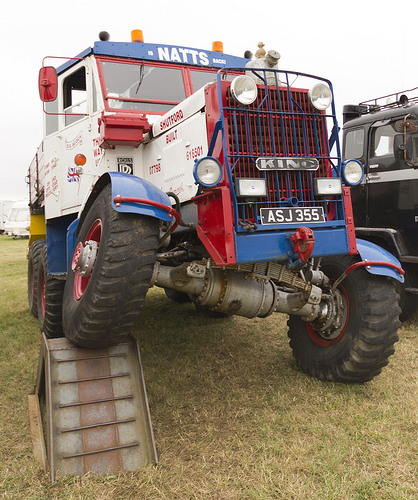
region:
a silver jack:
[38, 335, 159, 472]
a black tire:
[290, 246, 398, 379]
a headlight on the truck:
[195, 159, 220, 185]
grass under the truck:
[161, 382, 415, 496]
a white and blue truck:
[24, 35, 401, 377]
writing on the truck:
[155, 47, 216, 64]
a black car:
[345, 96, 416, 248]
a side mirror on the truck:
[39, 59, 88, 114]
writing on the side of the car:
[32, 120, 229, 203]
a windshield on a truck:
[101, 57, 186, 109]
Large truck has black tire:
[21, 27, 403, 382]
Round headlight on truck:
[229, 76, 258, 105]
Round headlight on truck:
[192, 157, 221, 186]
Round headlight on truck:
[342, 159, 363, 184]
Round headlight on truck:
[307, 82, 332, 113]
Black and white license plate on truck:
[260, 207, 326, 223]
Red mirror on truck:
[39, 66, 58, 99]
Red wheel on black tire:
[71, 218, 102, 301]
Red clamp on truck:
[292, 224, 315, 263]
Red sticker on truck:
[156, 107, 185, 130]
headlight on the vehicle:
[185, 151, 222, 186]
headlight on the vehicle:
[338, 159, 368, 190]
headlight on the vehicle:
[219, 77, 260, 103]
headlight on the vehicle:
[306, 90, 337, 115]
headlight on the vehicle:
[235, 180, 272, 192]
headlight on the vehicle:
[315, 178, 340, 198]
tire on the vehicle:
[57, 204, 169, 346]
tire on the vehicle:
[297, 273, 397, 403]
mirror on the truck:
[31, 62, 65, 107]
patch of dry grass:
[233, 454, 262, 482]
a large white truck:
[24, 30, 403, 385]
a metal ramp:
[24, 331, 157, 482]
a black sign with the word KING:
[256, 157, 318, 169]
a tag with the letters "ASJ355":
[257, 206, 325, 225]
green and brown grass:
[0, 231, 416, 499]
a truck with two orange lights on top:
[24, 28, 402, 384]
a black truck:
[336, 83, 416, 320]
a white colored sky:
[0, 1, 416, 202]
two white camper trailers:
[0, 201, 31, 241]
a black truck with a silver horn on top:
[335, 84, 415, 318]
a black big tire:
[51, 177, 171, 362]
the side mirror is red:
[15, 49, 66, 112]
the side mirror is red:
[24, 50, 81, 134]